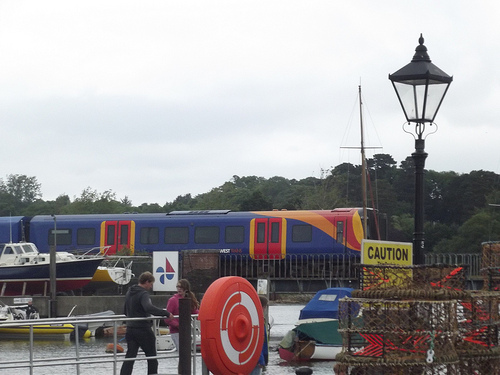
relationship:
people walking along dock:
[111, 266, 205, 367] [0, 302, 342, 373]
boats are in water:
[260, 277, 498, 373] [0, 317, 365, 370]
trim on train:
[320, 208, 365, 254] [0, 197, 400, 289]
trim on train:
[336, 208, 364, 251] [0, 197, 400, 289]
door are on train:
[253, 219, 282, 260] [2, 204, 392, 284]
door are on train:
[253, 219, 282, 260] [0, 197, 400, 289]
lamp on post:
[387, 28, 457, 123] [383, 25, 453, 374]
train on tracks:
[0, 205, 389, 308] [7, 276, 368, 337]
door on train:
[253, 219, 282, 260] [0, 207, 387, 256]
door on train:
[104, 221, 129, 251] [0, 207, 387, 256]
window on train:
[161, 223, 191, 246] [0, 207, 387, 256]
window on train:
[193, 222, 221, 245] [0, 207, 387, 256]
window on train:
[224, 224, 247, 245] [0, 205, 391, 260]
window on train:
[289, 222, 312, 242] [0, 205, 391, 260]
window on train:
[77, 228, 97, 248] [0, 207, 387, 256]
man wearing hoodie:
[118, 270, 174, 372] [121, 283, 169, 327]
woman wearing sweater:
[166, 279, 200, 352] [164, 291, 200, 331]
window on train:
[46, 229, 72, 246] [0, 207, 387, 256]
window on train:
[77, 228, 94, 245] [0, 205, 391, 260]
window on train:
[105, 223, 115, 246] [0, 207, 387, 256]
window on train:
[117, 223, 127, 247] [0, 207, 387, 256]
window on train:
[137, 225, 157, 245] [0, 207, 387, 256]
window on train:
[161, 227, 189, 244] [0, 207, 387, 256]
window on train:
[193, 222, 221, 245] [0, 205, 391, 260]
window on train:
[251, 216, 267, 256] [3, 204, 370, 277]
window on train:
[272, 218, 283, 240] [1, 213, 379, 274]